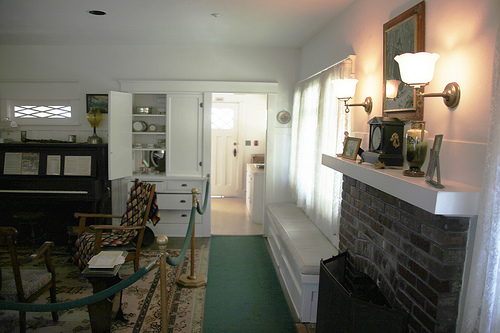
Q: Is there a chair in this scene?
A: Yes, there is a chair.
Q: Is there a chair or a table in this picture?
A: Yes, there is a chair.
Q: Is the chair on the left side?
A: Yes, the chair is on the left of the image.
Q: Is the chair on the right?
A: No, the chair is on the left of the image.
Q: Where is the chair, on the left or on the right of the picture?
A: The chair is on the left of the image.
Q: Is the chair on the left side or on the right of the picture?
A: The chair is on the left of the image.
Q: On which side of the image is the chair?
A: The chair is on the left of the image.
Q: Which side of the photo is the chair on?
A: The chair is on the left of the image.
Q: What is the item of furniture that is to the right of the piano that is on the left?
A: The piece of furniture is a chair.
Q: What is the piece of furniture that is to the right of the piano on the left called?
A: The piece of furniture is a chair.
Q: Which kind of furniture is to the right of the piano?
A: The piece of furniture is a chair.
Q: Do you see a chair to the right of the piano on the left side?
A: Yes, there is a chair to the right of the piano.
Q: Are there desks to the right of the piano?
A: No, there is a chair to the right of the piano.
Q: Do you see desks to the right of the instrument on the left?
A: No, there is a chair to the right of the piano.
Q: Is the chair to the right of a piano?
A: Yes, the chair is to the right of a piano.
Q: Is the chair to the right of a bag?
A: No, the chair is to the right of a piano.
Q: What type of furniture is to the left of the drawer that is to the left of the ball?
A: The piece of furniture is a chair.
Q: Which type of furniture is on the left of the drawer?
A: The piece of furniture is a chair.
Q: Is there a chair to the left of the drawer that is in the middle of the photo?
A: Yes, there is a chair to the left of the drawer.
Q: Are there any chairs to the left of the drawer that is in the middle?
A: Yes, there is a chair to the left of the drawer.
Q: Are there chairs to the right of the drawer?
A: No, the chair is to the left of the drawer.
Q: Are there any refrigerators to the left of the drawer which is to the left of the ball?
A: No, there is a chair to the left of the drawer.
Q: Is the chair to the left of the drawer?
A: Yes, the chair is to the left of the drawer.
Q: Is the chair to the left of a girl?
A: No, the chair is to the left of the drawer.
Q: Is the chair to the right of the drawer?
A: No, the chair is to the left of the drawer.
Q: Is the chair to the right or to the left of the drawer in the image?
A: The chair is to the left of the drawer.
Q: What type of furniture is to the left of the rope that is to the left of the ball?
A: The piece of furniture is a chair.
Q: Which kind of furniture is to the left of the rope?
A: The piece of furniture is a chair.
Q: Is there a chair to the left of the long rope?
A: Yes, there is a chair to the left of the rope.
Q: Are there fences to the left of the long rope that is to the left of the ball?
A: No, there is a chair to the left of the rope.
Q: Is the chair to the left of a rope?
A: Yes, the chair is to the left of a rope.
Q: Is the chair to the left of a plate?
A: No, the chair is to the left of a rope.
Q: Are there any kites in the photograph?
A: No, there are no kites.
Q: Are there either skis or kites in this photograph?
A: No, there are no kites or skis.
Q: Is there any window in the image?
A: Yes, there is a window.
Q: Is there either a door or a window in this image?
A: Yes, there is a window.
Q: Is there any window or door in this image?
A: Yes, there is a window.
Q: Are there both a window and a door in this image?
A: Yes, there are both a window and a door.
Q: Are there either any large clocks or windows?
A: Yes, there is a large window.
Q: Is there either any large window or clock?
A: Yes, there is a large window.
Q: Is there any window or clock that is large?
A: Yes, the window is large.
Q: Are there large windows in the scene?
A: Yes, there is a large window.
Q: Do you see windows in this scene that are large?
A: Yes, there is a window that is large.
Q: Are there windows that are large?
A: Yes, there is a window that is large.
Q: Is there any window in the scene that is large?
A: Yes, there is a window that is large.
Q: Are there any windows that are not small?
A: Yes, there is a large window.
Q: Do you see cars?
A: No, there are no cars.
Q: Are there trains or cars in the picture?
A: No, there are no cars or trains.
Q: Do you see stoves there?
A: No, there are no stoves.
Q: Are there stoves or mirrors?
A: No, there are no stoves or mirrors.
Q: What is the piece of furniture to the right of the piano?
A: The piece of furniture is a drawer.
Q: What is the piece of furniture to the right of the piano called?
A: The piece of furniture is a drawer.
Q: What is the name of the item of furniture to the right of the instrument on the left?
A: The piece of furniture is a drawer.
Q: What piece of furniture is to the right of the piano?
A: The piece of furniture is a drawer.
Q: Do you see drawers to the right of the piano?
A: Yes, there is a drawer to the right of the piano.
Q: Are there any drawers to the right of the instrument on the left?
A: Yes, there is a drawer to the right of the piano.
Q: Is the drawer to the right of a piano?
A: Yes, the drawer is to the right of a piano.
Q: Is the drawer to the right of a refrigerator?
A: No, the drawer is to the right of a piano.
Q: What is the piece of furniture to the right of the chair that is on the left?
A: The piece of furniture is a drawer.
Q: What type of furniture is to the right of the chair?
A: The piece of furniture is a drawer.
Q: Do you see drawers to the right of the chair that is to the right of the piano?
A: Yes, there is a drawer to the right of the chair.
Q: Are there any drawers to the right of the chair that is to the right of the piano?
A: Yes, there is a drawer to the right of the chair.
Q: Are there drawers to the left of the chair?
A: No, the drawer is to the right of the chair.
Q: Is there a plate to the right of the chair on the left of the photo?
A: No, there is a drawer to the right of the chair.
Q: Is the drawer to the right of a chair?
A: Yes, the drawer is to the right of a chair.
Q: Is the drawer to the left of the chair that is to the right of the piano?
A: No, the drawer is to the right of the chair.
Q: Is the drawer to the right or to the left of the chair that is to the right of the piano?
A: The drawer is to the right of the chair.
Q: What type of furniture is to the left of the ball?
A: The piece of furniture is a drawer.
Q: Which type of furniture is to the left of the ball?
A: The piece of furniture is a drawer.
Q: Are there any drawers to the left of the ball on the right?
A: Yes, there is a drawer to the left of the ball.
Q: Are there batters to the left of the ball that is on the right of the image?
A: No, there is a drawer to the left of the ball.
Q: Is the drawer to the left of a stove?
A: No, the drawer is to the left of the ball.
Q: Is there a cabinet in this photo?
A: Yes, there is a cabinet.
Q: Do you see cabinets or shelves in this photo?
A: Yes, there is a cabinet.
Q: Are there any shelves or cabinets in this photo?
A: Yes, there is a cabinet.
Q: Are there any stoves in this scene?
A: No, there are no stoves.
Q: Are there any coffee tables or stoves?
A: No, there are no stoves or coffee tables.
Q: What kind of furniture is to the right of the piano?
A: The piece of furniture is a cabinet.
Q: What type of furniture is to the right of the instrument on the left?
A: The piece of furniture is a cabinet.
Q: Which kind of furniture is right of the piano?
A: The piece of furniture is a cabinet.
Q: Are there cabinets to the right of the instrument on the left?
A: Yes, there is a cabinet to the right of the piano.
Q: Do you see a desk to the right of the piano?
A: No, there is a cabinet to the right of the piano.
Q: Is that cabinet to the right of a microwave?
A: No, the cabinet is to the right of a piano.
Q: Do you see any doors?
A: Yes, there is a door.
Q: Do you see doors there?
A: Yes, there is a door.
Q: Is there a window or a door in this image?
A: Yes, there is a door.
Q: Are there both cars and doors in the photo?
A: No, there is a door but no cars.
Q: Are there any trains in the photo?
A: No, there are no trains.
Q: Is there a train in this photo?
A: No, there are no trains.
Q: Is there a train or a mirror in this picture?
A: No, there are no trains or mirrors.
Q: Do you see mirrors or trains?
A: No, there are no trains or mirrors.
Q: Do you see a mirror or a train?
A: No, there are no trains or mirrors.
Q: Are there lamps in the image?
A: Yes, there is a lamp.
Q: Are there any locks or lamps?
A: Yes, there is a lamp.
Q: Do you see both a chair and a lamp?
A: Yes, there are both a lamp and a chair.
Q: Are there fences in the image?
A: No, there are no fences.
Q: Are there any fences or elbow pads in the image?
A: No, there are no fences or elbow pads.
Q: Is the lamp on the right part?
A: Yes, the lamp is on the right of the image.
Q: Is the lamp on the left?
A: No, the lamp is on the right of the image.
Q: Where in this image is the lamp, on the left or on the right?
A: The lamp is on the right of the image.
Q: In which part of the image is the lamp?
A: The lamp is on the right of the image.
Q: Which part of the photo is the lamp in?
A: The lamp is on the right of the image.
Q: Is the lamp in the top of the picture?
A: Yes, the lamp is in the top of the image.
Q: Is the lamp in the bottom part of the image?
A: No, the lamp is in the top of the image.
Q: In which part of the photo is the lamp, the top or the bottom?
A: The lamp is in the top of the image.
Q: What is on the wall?
A: The lamp is on the wall.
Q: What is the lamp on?
A: The lamp is on the wall.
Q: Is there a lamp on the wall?
A: Yes, there is a lamp on the wall.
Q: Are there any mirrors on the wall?
A: No, there is a lamp on the wall.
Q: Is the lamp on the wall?
A: Yes, the lamp is on the wall.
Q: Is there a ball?
A: Yes, there is a ball.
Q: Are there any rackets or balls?
A: Yes, there is a ball.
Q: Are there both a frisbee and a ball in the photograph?
A: No, there is a ball but no frisbees.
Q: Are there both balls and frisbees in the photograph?
A: No, there is a ball but no frisbees.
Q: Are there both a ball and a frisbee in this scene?
A: No, there is a ball but no frisbees.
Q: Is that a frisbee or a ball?
A: That is a ball.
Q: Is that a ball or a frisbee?
A: That is a ball.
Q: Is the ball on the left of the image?
A: No, the ball is on the right of the image.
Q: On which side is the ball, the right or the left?
A: The ball is on the right of the image.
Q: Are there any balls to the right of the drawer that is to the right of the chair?
A: Yes, there is a ball to the right of the drawer.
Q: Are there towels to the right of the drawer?
A: No, there is a ball to the right of the drawer.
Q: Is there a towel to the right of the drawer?
A: No, there is a ball to the right of the drawer.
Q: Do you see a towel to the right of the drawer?
A: No, there is a ball to the right of the drawer.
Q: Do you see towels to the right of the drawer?
A: No, there is a ball to the right of the drawer.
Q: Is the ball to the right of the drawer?
A: Yes, the ball is to the right of the drawer.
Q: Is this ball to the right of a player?
A: No, the ball is to the right of the drawer.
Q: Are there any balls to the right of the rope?
A: Yes, there is a ball to the right of the rope.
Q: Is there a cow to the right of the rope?
A: No, there is a ball to the right of the rope.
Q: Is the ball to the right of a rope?
A: Yes, the ball is to the right of a rope.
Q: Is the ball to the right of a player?
A: No, the ball is to the right of a rope.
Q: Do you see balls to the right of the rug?
A: Yes, there is a ball to the right of the rug.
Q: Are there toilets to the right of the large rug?
A: No, there is a ball to the right of the rug.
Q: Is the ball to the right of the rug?
A: Yes, the ball is to the right of the rug.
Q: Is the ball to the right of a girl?
A: No, the ball is to the right of the rug.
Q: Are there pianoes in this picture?
A: Yes, there is a piano.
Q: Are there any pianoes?
A: Yes, there is a piano.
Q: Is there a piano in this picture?
A: Yes, there is a piano.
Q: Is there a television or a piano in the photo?
A: Yes, there is a piano.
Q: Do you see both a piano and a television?
A: No, there is a piano but no televisions.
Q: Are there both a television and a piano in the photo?
A: No, there is a piano but no televisions.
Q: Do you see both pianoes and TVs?
A: No, there is a piano but no televisions.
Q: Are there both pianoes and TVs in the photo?
A: No, there is a piano but no televisions.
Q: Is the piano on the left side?
A: Yes, the piano is on the left of the image.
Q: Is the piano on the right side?
A: No, the piano is on the left of the image.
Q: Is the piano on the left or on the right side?
A: The piano is on the left of the image.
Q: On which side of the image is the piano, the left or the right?
A: The piano is on the left of the image.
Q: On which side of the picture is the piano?
A: The piano is on the left of the image.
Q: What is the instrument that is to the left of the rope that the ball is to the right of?
A: The instrument is a piano.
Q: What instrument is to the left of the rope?
A: The instrument is a piano.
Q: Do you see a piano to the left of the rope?
A: Yes, there is a piano to the left of the rope.